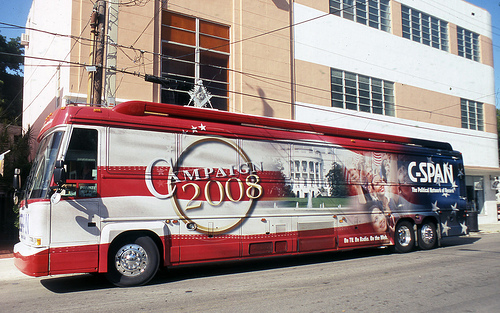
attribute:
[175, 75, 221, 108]
symbol — white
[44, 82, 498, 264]
bus — red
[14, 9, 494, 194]
building — large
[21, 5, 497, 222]
building — white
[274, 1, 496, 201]
building — white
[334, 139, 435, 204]
bus — white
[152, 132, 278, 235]
circle — gold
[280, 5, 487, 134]
building — white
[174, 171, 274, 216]
2008 — gold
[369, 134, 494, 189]
logo — white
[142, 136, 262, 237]
campaign 2008 — red, white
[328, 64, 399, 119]
window — large